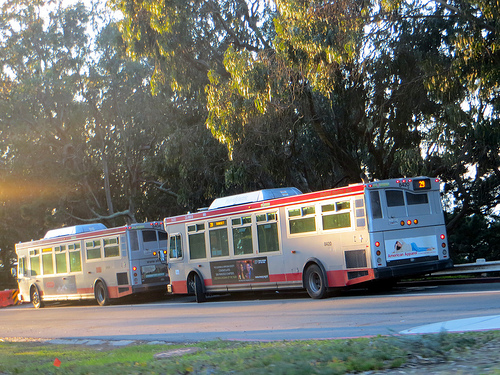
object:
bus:
[9, 216, 164, 307]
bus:
[156, 175, 450, 303]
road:
[0, 289, 498, 342]